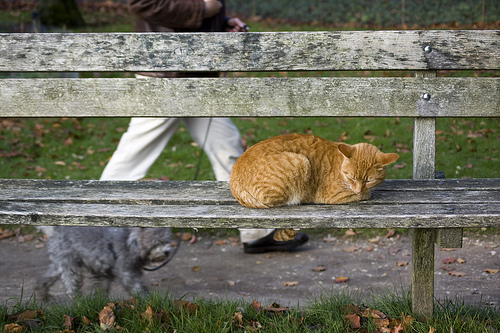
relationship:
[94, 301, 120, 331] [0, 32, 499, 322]
leaf laying on ground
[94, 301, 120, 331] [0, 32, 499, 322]
leaf on ground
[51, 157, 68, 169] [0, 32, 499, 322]
leaf laying on ground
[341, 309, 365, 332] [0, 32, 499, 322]
leaf laying on ground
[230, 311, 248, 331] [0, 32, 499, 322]
leaf laying on ground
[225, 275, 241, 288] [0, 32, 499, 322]
leaf laying on ground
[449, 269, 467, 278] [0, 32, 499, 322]
leaf laying on ground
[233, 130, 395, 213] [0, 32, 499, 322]
cat sleeping on bench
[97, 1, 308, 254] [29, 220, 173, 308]
person walking dog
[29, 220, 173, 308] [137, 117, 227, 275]
dog on leash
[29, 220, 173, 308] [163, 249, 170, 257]
dog has nose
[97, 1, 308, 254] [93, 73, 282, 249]
person wearing pants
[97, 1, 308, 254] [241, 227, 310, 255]
person wearing sandal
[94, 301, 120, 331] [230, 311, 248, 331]
leaf scattered next to leaf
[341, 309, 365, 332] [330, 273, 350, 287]
leaf scattered next to leaf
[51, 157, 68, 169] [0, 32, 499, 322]
leaf scattered on ground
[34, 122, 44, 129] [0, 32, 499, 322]
leaf laying on ground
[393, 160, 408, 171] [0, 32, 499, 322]
leaf laying on ground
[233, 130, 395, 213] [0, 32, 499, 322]
cat sitting on bench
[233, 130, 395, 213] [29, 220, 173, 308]
cat suspiciously eyeing dog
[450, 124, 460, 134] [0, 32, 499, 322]
leaf on ground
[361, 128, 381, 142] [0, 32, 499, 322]
leaf on ground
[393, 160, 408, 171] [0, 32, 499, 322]
leaf on ground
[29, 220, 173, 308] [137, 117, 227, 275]
dog attached to leash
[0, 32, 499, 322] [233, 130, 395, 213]
bench occupied by cat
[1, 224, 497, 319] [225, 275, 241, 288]
sidewalk has leaf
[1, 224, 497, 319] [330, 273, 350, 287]
sidewalk has leaf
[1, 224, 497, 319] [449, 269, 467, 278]
sidewalk has leaf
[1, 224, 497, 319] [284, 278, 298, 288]
sidewalk has leaf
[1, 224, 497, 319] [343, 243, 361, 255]
sidewalk has leaf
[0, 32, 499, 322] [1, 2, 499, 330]
ground in park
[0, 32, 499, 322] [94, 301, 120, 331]
ground covered in leaf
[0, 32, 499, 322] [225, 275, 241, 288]
ground covered in leaf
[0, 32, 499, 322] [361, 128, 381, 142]
ground covered in leaf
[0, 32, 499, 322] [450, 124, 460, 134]
ground covered in leaf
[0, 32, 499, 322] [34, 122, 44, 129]
ground covered in leaf